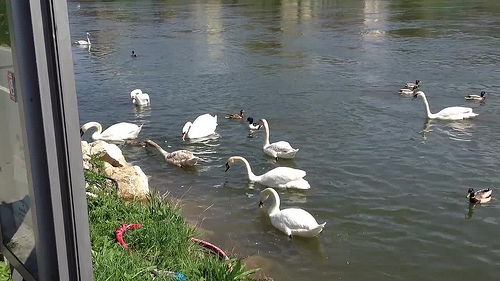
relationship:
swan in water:
[251, 183, 332, 247] [68, 0, 499, 280]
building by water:
[1, 0, 96, 279] [68, 0, 499, 280]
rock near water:
[104, 162, 152, 199] [68, 0, 499, 280]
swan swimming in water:
[251, 183, 332, 247] [68, 0, 499, 280]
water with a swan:
[68, 0, 499, 280] [251, 183, 332, 247]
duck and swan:
[464, 184, 493, 204] [251, 183, 332, 247]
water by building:
[68, 0, 499, 280] [1, 0, 96, 279]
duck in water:
[464, 184, 493, 204] [68, 0, 499, 280]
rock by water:
[104, 162, 152, 199] [68, 0, 499, 280]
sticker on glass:
[7, 71, 19, 103] [2, 0, 38, 280]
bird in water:
[220, 151, 313, 195] [68, 0, 499, 280]